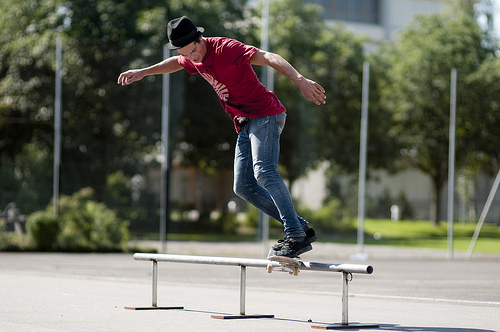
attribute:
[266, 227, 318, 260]
footwear — black, athletic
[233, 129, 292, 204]
jeans — blue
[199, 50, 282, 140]
shirt — red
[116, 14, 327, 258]
man — black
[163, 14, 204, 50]
hat — fedora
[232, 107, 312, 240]
jeans — blue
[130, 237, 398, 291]
tube — metal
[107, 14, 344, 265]
man — young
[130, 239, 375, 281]
metal rail — low, white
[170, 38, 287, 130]
shirt — red, short-sleeved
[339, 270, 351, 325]
pole — big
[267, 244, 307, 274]
skateboard — wooden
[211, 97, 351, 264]
pants — blue, denim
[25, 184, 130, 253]
bush — low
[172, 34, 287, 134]
tee shirt — red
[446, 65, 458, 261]
pole — metal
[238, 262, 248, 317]
pole — big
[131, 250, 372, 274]
pole — big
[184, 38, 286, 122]
shirt — red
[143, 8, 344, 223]
male — young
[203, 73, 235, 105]
design — white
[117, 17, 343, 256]
shirt — red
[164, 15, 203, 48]
hat — black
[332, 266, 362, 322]
stand — metal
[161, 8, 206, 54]
fedora — black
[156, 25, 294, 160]
shirt — red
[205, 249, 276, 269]
pole — metal